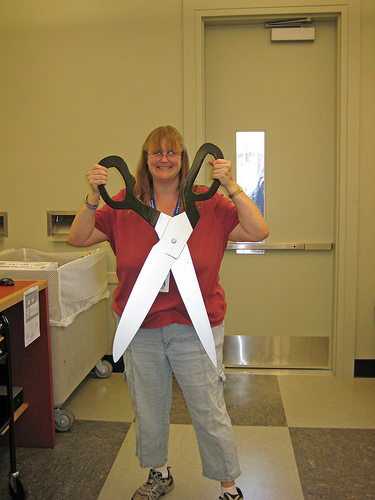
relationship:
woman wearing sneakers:
[67, 128, 278, 497] [133, 471, 185, 498]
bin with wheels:
[4, 240, 124, 401] [53, 403, 78, 434]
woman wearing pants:
[67, 128, 278, 497] [115, 312, 257, 484]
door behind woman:
[196, 18, 346, 383] [67, 128, 278, 497]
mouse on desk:
[0, 276, 18, 288] [0, 284, 62, 453]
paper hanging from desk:
[19, 290, 48, 348] [0, 284, 62, 453]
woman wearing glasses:
[67, 128, 278, 497] [154, 148, 177, 159]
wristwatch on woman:
[83, 195, 101, 213] [67, 128, 278, 497]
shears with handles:
[72, 144, 245, 375] [181, 141, 228, 229]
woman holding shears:
[67, 128, 278, 497] [72, 144, 245, 375]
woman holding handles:
[67, 128, 278, 497] [181, 141, 228, 229]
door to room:
[196, 18, 346, 383] [3, 2, 374, 499]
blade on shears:
[169, 252, 224, 370] [72, 144, 245, 375]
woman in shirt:
[67, 128, 278, 497] [98, 181, 234, 327]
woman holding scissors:
[67, 128, 278, 497] [72, 144, 245, 375]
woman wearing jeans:
[67, 128, 278, 497] [115, 312, 257, 484]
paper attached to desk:
[19, 290, 48, 348] [0, 284, 62, 453]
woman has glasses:
[67, 128, 278, 497] [154, 148, 177, 159]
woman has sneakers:
[67, 128, 278, 497] [133, 471, 185, 498]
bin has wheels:
[4, 240, 124, 401] [53, 403, 78, 434]